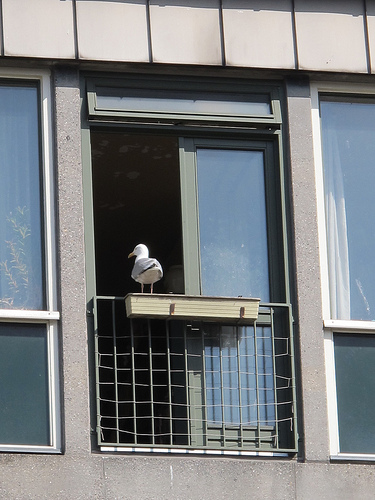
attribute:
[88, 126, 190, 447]
interior — dark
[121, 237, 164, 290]
bird — facing the interior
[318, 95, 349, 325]
curtain — white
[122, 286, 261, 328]
box — flower box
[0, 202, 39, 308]
plant — brown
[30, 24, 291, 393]
building — rough, gray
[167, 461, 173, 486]
mark — white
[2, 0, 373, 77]
tile — tile pattern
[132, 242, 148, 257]
head — white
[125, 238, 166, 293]
bird — white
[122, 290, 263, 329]
box — flower box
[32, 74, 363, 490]
frame — white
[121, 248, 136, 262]
beak — yellow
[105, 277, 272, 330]
block — wooden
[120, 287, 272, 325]
box — flower box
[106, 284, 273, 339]
box — flower box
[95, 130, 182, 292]
interior — dark